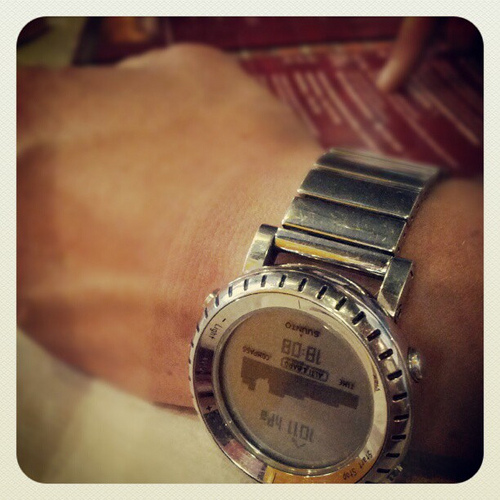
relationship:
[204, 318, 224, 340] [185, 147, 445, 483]
word on silver watch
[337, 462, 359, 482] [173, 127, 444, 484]
stop on watch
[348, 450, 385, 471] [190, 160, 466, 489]
start on watch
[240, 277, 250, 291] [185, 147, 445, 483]
line on silver watch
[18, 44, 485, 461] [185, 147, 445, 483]
man wearing silver watch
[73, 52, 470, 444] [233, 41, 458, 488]
man on table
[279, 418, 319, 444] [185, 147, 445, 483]
time on silver watch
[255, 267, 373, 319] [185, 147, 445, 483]
silver rim on silver watch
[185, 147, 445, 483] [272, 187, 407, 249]
silver watch on link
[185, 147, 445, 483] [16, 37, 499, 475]
silver watch on arm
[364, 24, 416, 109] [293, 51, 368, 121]
finger touching paper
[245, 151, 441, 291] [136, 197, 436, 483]
bracket on watch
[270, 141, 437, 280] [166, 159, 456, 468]
band on watch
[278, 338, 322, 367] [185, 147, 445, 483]
black letters on silver watch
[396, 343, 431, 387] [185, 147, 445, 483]
knob on silver watch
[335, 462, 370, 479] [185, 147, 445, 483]
tent on silver watch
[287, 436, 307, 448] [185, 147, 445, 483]
arrow on silver watch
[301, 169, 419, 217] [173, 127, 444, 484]
watchlink on watch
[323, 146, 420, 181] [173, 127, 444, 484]
watchlink on watch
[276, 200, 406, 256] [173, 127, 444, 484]
watchlink on watch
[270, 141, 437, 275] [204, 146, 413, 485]
band on watch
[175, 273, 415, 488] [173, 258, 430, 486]
engraving on watch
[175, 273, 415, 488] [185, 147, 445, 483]
engraving on silver watch